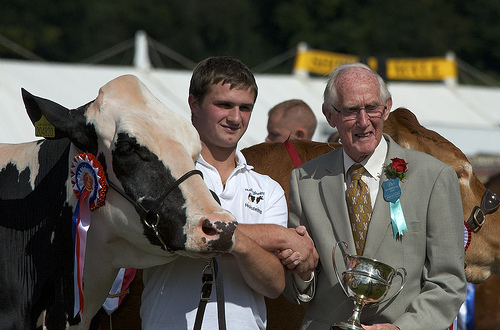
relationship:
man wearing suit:
[274, 55, 483, 327] [277, 127, 476, 328]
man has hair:
[274, 55, 468, 329] [316, 59, 343, 105]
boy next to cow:
[140, 57, 320, 328] [0, 70, 240, 328]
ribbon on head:
[65, 152, 109, 323] [22, 72, 237, 270]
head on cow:
[22, 72, 237, 270] [0, 70, 240, 328]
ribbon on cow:
[65, 152, 109, 323] [0, 70, 240, 328]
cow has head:
[14, 75, 259, 326] [22, 72, 237, 270]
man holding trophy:
[274, 55, 468, 329] [331, 241, 406, 328]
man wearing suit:
[274, 55, 468, 329] [288, 130, 467, 328]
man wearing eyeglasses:
[274, 55, 468, 329] [337, 103, 387, 123]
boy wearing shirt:
[140, 57, 319, 330] [137, 150, 287, 325]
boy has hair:
[140, 57, 319, 330] [188, 55, 258, 118]